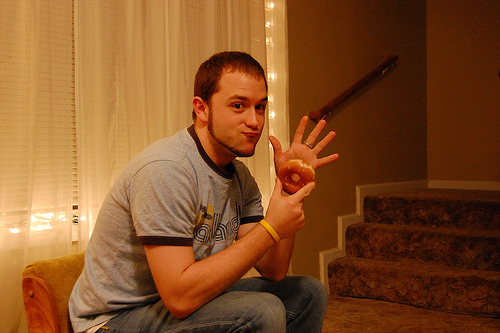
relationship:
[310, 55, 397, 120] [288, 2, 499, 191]
rail stuck on wall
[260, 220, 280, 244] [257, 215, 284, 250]
bracelet on wrist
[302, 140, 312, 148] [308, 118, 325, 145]
ring on mans finger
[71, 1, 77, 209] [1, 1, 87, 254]
blinds on window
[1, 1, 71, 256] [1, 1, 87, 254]
curtain over window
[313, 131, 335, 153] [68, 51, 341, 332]
finger of man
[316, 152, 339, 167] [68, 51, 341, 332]
finger of man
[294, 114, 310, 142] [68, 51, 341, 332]
finger of man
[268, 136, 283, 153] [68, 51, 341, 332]
finger of man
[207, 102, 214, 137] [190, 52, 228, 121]
beard and mans hair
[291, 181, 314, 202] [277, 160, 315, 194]
index finger holding doughnut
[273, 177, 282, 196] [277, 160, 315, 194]
thumb finger on doughnut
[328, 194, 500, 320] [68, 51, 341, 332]
stairs next to man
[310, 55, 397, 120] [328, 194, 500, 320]
rail above stairs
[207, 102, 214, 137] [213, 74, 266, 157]
beard on mans face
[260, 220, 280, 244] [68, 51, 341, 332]
bracelet on wrist of man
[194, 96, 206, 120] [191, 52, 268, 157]
ear on mans head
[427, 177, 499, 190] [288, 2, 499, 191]
molding at base of wall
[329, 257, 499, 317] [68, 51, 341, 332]
stair by side of man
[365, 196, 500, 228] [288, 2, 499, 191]
stair along wall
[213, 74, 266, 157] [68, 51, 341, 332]
face on man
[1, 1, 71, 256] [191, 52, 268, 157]
curtain behind mans head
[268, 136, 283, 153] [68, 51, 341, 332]
finger on man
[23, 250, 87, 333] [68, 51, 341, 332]
chair underneath man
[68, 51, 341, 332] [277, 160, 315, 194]
man holding onto a doughnut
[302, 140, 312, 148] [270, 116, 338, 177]
ring on hand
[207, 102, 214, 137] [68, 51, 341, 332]
beard on man